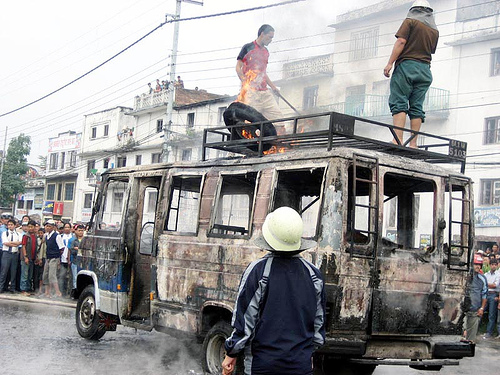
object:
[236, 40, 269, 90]
shirt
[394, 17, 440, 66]
shirt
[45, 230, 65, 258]
shirt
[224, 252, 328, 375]
shirt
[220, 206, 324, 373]
man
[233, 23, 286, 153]
others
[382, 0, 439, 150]
others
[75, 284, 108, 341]
tire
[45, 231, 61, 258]
vest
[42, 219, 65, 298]
man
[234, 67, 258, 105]
flame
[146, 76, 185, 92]
people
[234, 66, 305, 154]
fire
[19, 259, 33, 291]
jeans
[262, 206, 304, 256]
head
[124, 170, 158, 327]
door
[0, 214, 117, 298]
person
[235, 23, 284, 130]
man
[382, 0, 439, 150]
man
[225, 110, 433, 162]
railing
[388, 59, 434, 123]
pants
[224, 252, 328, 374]
jacket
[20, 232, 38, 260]
vest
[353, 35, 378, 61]
bars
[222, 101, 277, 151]
tire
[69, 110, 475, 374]
car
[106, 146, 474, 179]
roof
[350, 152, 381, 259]
ladder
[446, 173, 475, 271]
ladder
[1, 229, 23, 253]
shirt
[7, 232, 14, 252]
tie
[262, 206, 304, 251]
hard hat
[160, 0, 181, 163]
utility pole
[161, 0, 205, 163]
pole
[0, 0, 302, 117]
wire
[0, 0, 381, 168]
sky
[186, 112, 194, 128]
window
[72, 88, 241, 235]
building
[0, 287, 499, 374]
street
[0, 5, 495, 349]
smoke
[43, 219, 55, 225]
hat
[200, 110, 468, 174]
platform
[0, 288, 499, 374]
pavement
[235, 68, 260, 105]
fire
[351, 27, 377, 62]
window